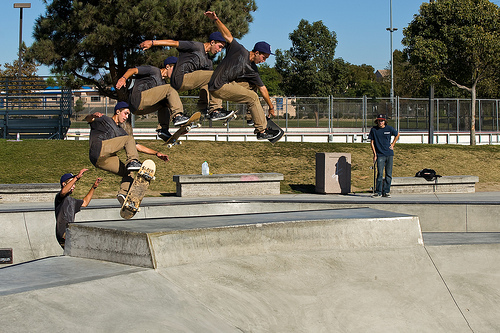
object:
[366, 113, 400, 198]
man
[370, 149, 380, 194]
skateboard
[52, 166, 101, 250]
man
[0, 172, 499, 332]
skate park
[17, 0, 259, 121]
trees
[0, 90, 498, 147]
fence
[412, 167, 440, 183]
backpack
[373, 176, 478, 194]
bench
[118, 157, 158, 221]
skateboard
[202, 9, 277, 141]
man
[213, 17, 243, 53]
arm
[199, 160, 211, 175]
container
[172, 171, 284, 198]
bench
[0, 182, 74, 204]
bench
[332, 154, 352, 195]
shadow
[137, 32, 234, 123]
man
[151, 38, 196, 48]
arm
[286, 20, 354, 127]
tree